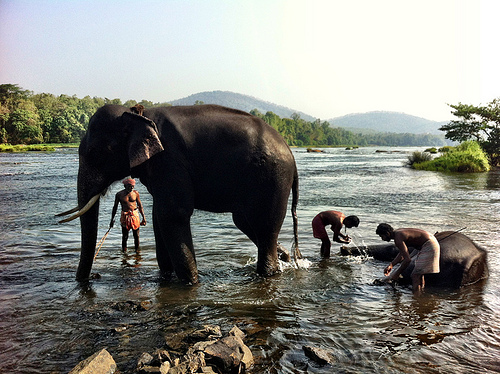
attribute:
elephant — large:
[50, 98, 304, 285]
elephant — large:
[30, 94, 374, 318]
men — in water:
[313, 202, 443, 305]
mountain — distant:
[329, 108, 449, 146]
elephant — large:
[60, 83, 340, 310]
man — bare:
[376, 227, 437, 286]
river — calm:
[1, 146, 499, 371]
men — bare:
[288, 189, 445, 297]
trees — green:
[4, 92, 119, 147]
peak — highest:
[114, 58, 366, 122]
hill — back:
[167, 88, 322, 128]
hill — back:
[326, 107, 447, 134]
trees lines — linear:
[0, 84, 455, 149]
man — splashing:
[313, 208, 360, 264]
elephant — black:
[60, 99, 300, 301]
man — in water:
[375, 220, 440, 296]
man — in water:
[310, 209, 360, 259]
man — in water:
[110, 177, 148, 260]